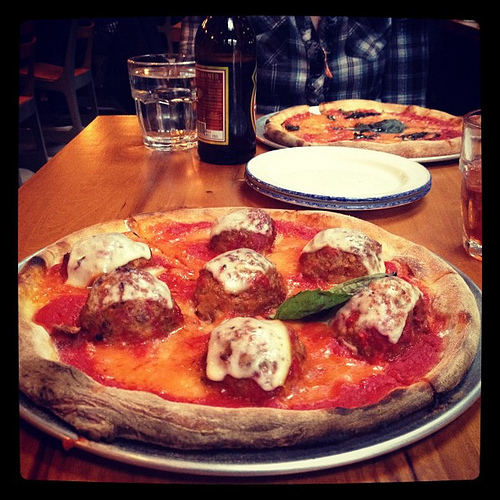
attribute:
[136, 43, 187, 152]
glass — clear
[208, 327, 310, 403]
meatball — large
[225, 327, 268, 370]
cheese — melted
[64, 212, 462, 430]
pizza — cooked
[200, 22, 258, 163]
bottle — dark, brown, alcohol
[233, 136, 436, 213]
plates — paper, white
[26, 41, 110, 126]
chairs — wooden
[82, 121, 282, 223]
table — brown, wood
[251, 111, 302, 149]
tray — metal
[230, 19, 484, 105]
person — sitting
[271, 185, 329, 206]
edges — blue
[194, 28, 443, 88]
shirt — plaid, blue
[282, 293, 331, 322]
leaf — green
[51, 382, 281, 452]
crust — baked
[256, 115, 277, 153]
plate — silver